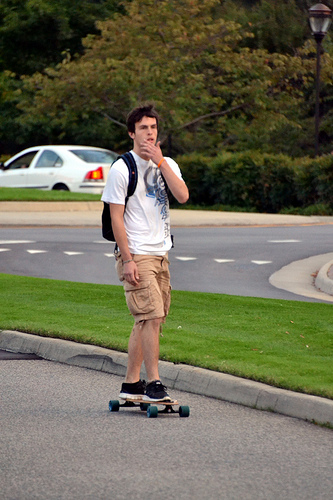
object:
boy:
[107, 106, 189, 403]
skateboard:
[106, 398, 190, 420]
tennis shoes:
[120, 380, 169, 404]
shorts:
[115, 249, 171, 324]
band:
[140, 138, 162, 163]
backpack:
[101, 151, 138, 237]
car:
[1, 143, 119, 195]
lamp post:
[306, 2, 332, 157]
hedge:
[159, 151, 332, 208]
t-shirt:
[100, 158, 184, 255]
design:
[143, 165, 168, 235]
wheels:
[148, 404, 158, 416]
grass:
[0, 271, 333, 400]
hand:
[140, 137, 164, 166]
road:
[0, 349, 331, 500]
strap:
[119, 151, 137, 202]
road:
[0, 220, 332, 299]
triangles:
[251, 257, 271, 269]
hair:
[125, 106, 158, 133]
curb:
[1, 327, 332, 427]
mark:
[62, 352, 130, 377]